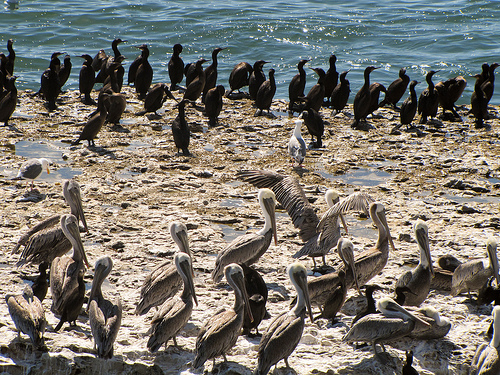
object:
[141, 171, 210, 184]
beach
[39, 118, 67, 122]
line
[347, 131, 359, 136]
twig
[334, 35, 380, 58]
water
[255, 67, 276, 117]
pelicans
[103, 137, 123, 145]
sand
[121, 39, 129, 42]
bill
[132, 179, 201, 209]
claw prints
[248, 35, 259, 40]
reflection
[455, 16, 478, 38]
foam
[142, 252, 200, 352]
seagull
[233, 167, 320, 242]
wings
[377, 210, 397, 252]
beak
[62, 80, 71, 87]
bubbles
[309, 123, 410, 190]
shore